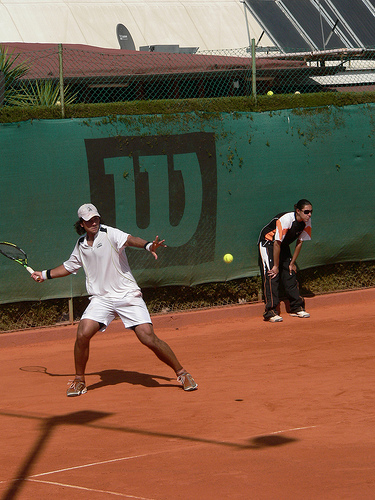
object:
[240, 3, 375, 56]
panel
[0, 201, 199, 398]
man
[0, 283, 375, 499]
court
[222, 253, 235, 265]
ball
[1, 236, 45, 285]
racket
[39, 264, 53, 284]
wristband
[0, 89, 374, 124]
grass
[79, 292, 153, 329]
shorts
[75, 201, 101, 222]
cap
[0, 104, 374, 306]
screen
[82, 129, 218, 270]
logo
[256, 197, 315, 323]
person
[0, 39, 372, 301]
fence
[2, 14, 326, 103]
building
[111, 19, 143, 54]
dish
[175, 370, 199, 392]
shoes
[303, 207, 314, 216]
glasses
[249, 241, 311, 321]
pants